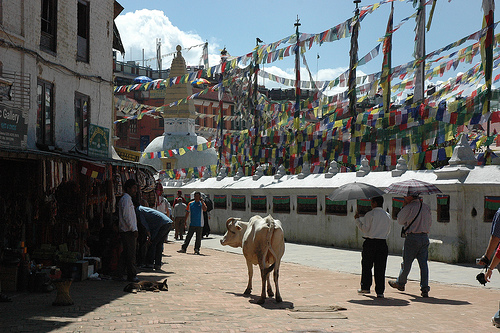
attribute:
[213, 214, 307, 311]
bull — white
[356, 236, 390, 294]
pants — black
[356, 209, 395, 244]
shirt — white, blue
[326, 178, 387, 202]
umbrella — grey, plaid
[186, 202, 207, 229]
shirt — blue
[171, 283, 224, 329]
street — reddish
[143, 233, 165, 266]
jeans — blue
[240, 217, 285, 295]
cow — white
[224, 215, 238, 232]
horn — curved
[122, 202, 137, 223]
t-shirt — white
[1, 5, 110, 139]
building — old, white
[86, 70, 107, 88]
wall — low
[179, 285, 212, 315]
bricks — concrete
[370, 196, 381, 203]
hair — black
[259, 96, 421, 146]
flags — multicolored, colorful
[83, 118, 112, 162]
sign — green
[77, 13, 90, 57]
window — closed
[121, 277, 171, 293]
dog — laying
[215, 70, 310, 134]
curtains — colorful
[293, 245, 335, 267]
pathway — brick